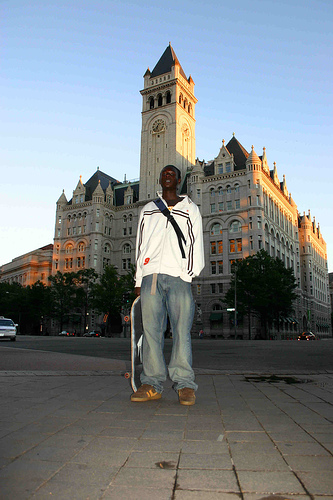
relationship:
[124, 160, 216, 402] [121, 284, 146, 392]
man standing next to a skateboard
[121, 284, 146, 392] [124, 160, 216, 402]
skateboard next to man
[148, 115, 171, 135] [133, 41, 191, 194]
clock on a tower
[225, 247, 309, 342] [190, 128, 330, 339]
tree by a building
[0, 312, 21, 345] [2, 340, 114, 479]
car in street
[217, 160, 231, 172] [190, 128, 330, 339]
window of a building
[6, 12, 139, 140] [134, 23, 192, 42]
sky in distance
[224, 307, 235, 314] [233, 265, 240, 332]
sign on a pole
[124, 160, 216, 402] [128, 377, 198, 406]
man wearing brown sneakers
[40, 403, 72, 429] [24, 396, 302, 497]
part of a sidewalk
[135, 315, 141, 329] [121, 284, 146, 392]
part of a skateboard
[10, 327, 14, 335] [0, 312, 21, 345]
part of a car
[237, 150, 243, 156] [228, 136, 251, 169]
part of a roof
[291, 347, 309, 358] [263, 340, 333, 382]
part of a roadway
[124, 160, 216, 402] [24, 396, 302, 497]
man standing on sidewalk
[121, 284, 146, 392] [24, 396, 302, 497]
skateboard on sidewalk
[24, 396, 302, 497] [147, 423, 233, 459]
sidewalk made of bricks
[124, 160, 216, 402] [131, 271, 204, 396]
man wearing jeans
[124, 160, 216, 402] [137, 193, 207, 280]
man wearing white jacket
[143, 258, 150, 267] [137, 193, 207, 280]
number on jacket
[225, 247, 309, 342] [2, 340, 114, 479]
tree across street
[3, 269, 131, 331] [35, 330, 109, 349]
trees line sidewalk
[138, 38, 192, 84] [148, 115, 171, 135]
spire with a clock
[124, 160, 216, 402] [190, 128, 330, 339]
man in front of a building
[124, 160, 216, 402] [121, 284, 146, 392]
man holding skateboard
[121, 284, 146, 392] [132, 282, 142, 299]
skateboard in a mans hand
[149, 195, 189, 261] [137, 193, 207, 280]
strap across a jacket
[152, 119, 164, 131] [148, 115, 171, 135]
face of a clock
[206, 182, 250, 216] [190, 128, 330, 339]
windows on a building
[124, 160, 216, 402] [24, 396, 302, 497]
man standing on a sidewalk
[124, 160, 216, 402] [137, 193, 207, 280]
man wearing a jacket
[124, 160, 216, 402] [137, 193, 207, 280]
man wearing a white jacket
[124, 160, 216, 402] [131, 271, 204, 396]
man wearing pants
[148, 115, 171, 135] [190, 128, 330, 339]
clock on a building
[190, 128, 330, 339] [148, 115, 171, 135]
building with a clock